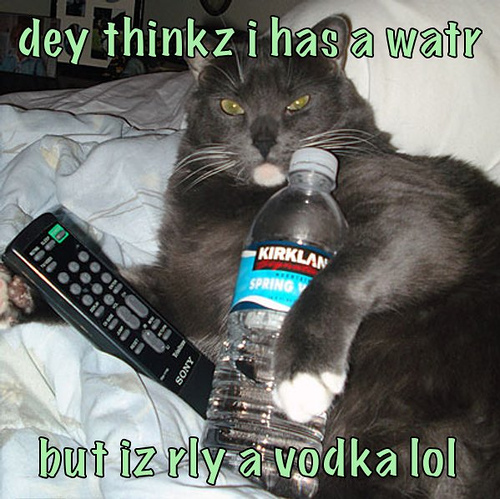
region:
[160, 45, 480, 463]
a cat with green eyes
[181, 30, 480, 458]
a big grey cat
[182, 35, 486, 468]
a grey cat with white hands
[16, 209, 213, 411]
a sony brand remote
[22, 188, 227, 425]
a black tv remote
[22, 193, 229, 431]
a black remote with grey buttons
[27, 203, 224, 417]
a black remote with green around a button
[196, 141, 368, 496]
a bottle of water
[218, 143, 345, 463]
a bottle with a blue label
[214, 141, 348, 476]
a plastic water bottle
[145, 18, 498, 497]
cat on the couch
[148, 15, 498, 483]
the cat is gray and white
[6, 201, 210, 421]
cat holding the remote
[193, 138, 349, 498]
cat holding the bottle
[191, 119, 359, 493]
bottle of water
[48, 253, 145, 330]
buttons on the remote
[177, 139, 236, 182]
whiskers on the cat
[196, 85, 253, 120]
eye of the cat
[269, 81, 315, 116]
eye of the cat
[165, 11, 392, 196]
head of the cat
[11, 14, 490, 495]
The cat is gray and white.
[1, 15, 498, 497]
The cat is holding a bottle of water.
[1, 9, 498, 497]
The cat is longhaired.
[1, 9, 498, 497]
The cat is holding a remote controller.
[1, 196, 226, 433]
The remote controller is black.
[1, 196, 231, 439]
The remote controller is a Sony brand.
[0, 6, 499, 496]
The cat is lying on a bed.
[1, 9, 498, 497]
The cat has green eyes.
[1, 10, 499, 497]
The cat is alert.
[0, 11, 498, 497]
The cat is awake.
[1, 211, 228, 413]
black Sony TV remote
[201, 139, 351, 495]
plastic water bottle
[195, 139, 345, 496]
Kirkland's bottled water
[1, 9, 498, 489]
gray cat holding a water bottle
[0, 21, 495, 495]
gray cat holding a remote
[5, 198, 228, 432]
tv remote with gray buttons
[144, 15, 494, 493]
adult cat with gray hair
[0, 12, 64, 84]
framed photo of a woman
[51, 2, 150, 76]
framed photo collage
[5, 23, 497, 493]
cat laying on a white comforter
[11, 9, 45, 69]
The letter is green.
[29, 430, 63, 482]
The letter is green.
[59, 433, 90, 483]
The letter is green.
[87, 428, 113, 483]
The letter is green.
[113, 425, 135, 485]
The letter is green.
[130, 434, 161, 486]
The letter is green.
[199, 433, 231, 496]
The letter is green.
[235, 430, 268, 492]
The letter is green.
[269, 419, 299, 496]
The letter is green.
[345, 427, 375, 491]
The letter is green.